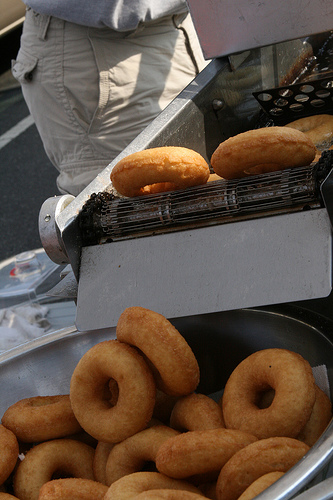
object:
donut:
[108, 143, 214, 199]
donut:
[210, 126, 315, 178]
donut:
[116, 305, 201, 395]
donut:
[222, 348, 316, 437]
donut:
[66, 335, 157, 445]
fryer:
[15, 0, 208, 201]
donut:
[152, 425, 261, 482]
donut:
[210, 434, 315, 500]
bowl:
[1, 304, 332, 498]